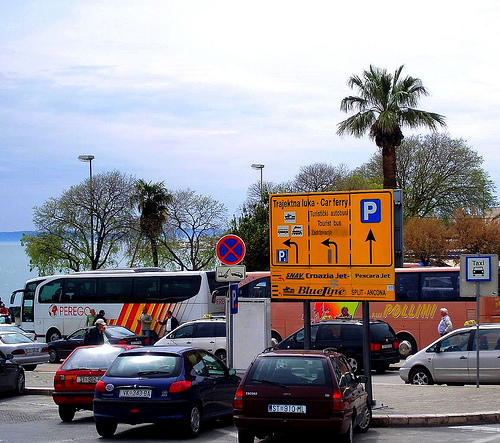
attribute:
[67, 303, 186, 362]
people — talking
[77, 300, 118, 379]
man — walking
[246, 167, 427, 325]
sign — road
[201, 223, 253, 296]
"x" — red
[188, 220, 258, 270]
sign — blue, circular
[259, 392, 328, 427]
license plate — European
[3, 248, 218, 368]
perego bus — large, white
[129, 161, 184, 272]
tree — palm tree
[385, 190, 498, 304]
trees — fluffy, orange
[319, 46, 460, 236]
tree — palm tree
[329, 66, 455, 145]
leaves — green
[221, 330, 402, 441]
car — maroon, four door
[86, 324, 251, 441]
car — blue, two door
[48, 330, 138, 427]
car — red, compact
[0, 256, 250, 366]
bus — white, long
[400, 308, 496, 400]
minivan — grey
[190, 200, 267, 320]
traffic sign — tow away zone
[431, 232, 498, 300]
taxi sign — trimmed in blue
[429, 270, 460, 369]
belly — big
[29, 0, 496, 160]
sky — cloudy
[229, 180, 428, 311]
steet sign — directional, orange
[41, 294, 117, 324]
word — red, "Perego:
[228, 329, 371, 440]
car — parked diagonally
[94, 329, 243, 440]
car — parked diagonally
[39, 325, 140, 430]
car — parked diagonally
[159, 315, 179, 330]
jacket — dark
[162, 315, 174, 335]
shirt — white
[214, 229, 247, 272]
x sign — blue, red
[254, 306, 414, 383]
mini van — dark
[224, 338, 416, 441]
car — red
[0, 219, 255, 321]
ocean — blue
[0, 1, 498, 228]
sky — cloudy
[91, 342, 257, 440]
car — blue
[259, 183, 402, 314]
road sign — yellow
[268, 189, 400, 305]
traffic sign — yellow